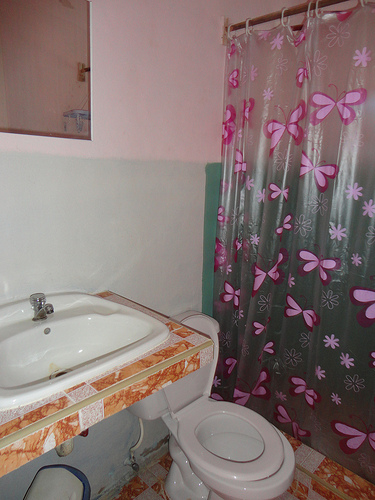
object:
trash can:
[23, 463, 90, 498]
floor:
[101, 395, 375, 500]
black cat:
[308, 83, 367, 125]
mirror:
[0, 0, 91, 142]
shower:
[207, 0, 374, 476]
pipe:
[55, 438, 75, 457]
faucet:
[28, 290, 55, 321]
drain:
[50, 368, 71, 379]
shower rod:
[226, 1, 349, 32]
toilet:
[118, 314, 298, 500]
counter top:
[0, 292, 212, 478]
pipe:
[125, 410, 145, 459]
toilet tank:
[127, 311, 219, 420]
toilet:
[127, 309, 297, 499]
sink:
[0, 296, 168, 413]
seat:
[176, 400, 284, 483]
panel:
[2, 3, 92, 138]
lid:
[158, 311, 219, 420]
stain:
[49, 363, 60, 373]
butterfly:
[210, 33, 375, 452]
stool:
[171, 400, 296, 499]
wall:
[0, 0, 297, 417]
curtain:
[209, 4, 375, 484]